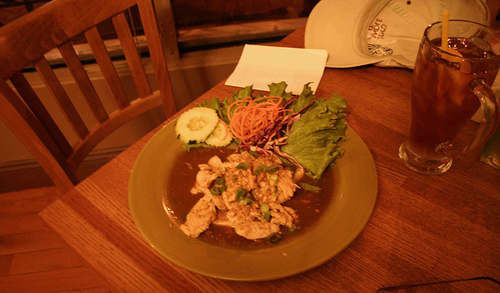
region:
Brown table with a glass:
[361, 93, 476, 253]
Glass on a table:
[420, 21, 488, 207]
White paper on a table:
[222, 30, 349, 166]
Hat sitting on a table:
[313, 1, 485, 75]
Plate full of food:
[121, 102, 368, 292]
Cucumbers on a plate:
[168, 86, 257, 149]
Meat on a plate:
[176, 144, 342, 256]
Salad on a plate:
[189, 79, 382, 165]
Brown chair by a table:
[7, 17, 218, 183]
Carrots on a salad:
[220, 96, 321, 150]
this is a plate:
[204, 249, 305, 269]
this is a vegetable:
[293, 123, 331, 153]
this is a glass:
[408, 61, 483, 146]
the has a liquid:
[423, 69, 463, 104]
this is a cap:
[338, 9, 406, 64]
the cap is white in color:
[323, 15, 350, 33]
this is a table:
[401, 172, 486, 242]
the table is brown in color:
[393, 199, 440, 233]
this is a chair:
[17, 19, 140, 119]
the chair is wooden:
[31, 15, 78, 46]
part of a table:
[357, 85, 400, 112]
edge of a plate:
[285, 253, 315, 275]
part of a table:
[375, 179, 420, 250]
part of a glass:
[413, 95, 438, 150]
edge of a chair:
[23, 137, 58, 182]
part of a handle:
[466, 120, 483, 153]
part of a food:
[228, 155, 274, 218]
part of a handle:
[446, 265, 485, 288]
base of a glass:
[398, 132, 432, 170]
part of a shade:
[391, 207, 438, 269]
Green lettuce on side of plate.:
[228, 81, 367, 231]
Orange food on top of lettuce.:
[225, 92, 290, 150]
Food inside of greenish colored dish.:
[141, 92, 295, 284]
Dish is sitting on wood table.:
[162, 147, 362, 284]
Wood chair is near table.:
[35, 22, 161, 164]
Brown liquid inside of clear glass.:
[406, 48, 480, 232]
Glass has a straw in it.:
[421, 12, 453, 64]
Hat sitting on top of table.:
[338, 15, 394, 110]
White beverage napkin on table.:
[226, 32, 326, 115]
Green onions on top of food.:
[198, 150, 299, 261]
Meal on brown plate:
[127, 85, 377, 277]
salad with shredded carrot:
[176, 79, 352, 172]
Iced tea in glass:
[396, 6, 497, 174]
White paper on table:
[223, 35, 324, 92]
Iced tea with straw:
[396, 11, 498, 176]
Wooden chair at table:
[0, 2, 177, 189]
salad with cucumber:
[171, 70, 351, 159]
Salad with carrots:
[172, 71, 342, 173]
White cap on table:
[301, 0, 479, 65]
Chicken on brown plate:
[170, 151, 306, 241]